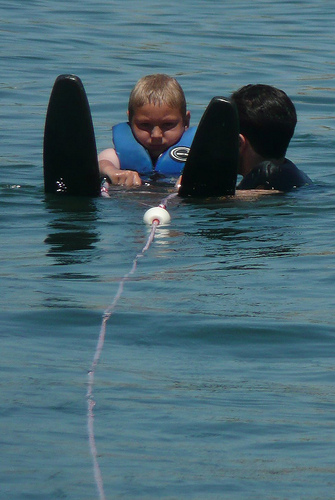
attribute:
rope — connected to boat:
[86, 257, 170, 294]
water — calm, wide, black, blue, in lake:
[151, 36, 272, 86]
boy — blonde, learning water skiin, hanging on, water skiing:
[106, 75, 203, 225]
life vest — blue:
[125, 143, 192, 186]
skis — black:
[16, 135, 104, 171]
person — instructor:
[222, 80, 325, 194]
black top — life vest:
[253, 164, 301, 187]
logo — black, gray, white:
[173, 143, 194, 161]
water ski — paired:
[206, 125, 235, 201]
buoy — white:
[145, 196, 168, 236]